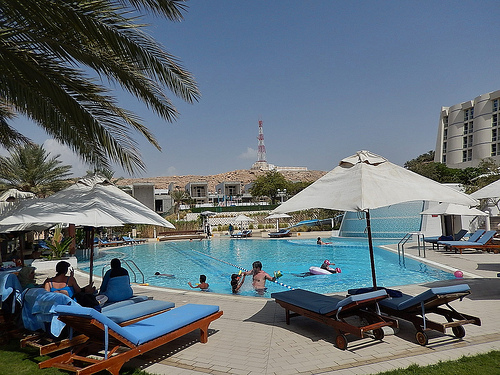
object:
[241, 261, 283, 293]
person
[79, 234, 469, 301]
pool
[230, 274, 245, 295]
person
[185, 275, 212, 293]
person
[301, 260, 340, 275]
person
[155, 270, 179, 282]
person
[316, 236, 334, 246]
person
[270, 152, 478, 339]
umbrella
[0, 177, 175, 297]
umbrella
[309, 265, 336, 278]
float toy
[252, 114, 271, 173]
pillar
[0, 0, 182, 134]
leaves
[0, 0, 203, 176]
tree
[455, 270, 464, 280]
ball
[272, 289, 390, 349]
lounge chair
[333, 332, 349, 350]
wheels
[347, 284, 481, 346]
lounge chair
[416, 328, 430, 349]
wheels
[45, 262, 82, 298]
woman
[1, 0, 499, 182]
sky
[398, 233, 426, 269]
railing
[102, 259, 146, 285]
railing